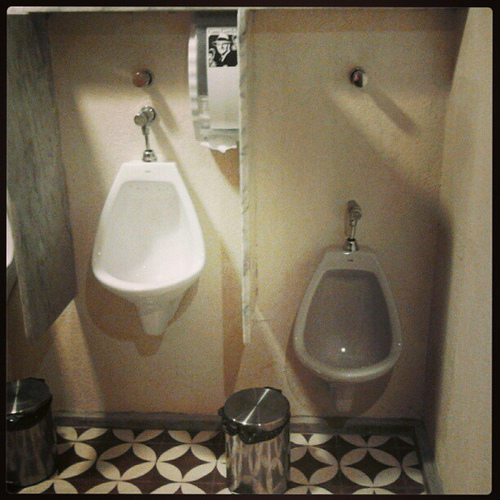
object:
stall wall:
[235, 0, 257, 345]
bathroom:
[0, 0, 500, 500]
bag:
[0, 374, 54, 433]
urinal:
[291, 251, 402, 383]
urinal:
[91, 161, 204, 336]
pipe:
[344, 200, 362, 251]